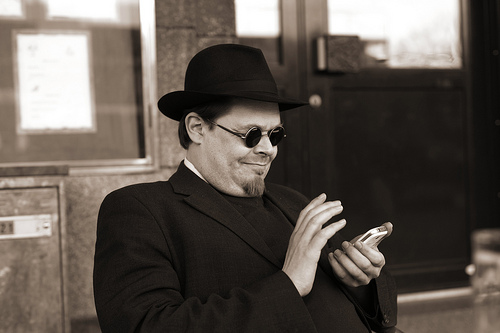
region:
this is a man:
[74, 55, 381, 332]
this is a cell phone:
[348, 227, 394, 257]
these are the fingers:
[285, 197, 345, 283]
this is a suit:
[140, 201, 232, 296]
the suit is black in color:
[154, 199, 206, 277]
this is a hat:
[202, 42, 273, 89]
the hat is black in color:
[210, 46, 263, 86]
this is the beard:
[246, 174, 264, 196]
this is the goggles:
[247, 123, 289, 146]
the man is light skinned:
[206, 140, 233, 170]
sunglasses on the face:
[183, 110, 290, 151]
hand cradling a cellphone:
[330, 212, 400, 289]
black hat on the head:
[145, 38, 330, 133]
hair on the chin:
[240, 174, 277, 201]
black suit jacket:
[59, 158, 409, 330]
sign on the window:
[5, 20, 125, 145]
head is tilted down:
[137, 38, 342, 220]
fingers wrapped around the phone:
[323, 238, 388, 281]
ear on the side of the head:
[184, 112, 210, 149]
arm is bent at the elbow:
[83, 182, 349, 332]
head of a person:
[156, 27, 300, 203]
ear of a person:
[171, 96, 211, 149]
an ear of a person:
[179, 107, 216, 170]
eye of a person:
[238, 121, 265, 156]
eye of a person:
[258, 130, 300, 152]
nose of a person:
[250, 135, 287, 159]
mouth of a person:
[237, 153, 282, 173]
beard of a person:
[232, 171, 287, 203]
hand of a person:
[253, 181, 355, 309]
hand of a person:
[329, 221, 408, 284]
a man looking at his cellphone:
[92, 33, 401, 330]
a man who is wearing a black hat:
[126, 28, 323, 201]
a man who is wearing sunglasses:
[145, 36, 327, 203]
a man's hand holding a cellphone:
[323, 213, 401, 295]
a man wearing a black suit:
[76, 38, 416, 328]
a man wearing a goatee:
[153, 32, 314, 217]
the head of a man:
[174, 95, 288, 200]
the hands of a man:
[268, 182, 403, 307]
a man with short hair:
[138, 39, 300, 201]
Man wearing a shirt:
[215, 178, 368, 331]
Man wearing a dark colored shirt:
[210, 182, 370, 331]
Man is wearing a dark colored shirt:
[207, 180, 374, 332]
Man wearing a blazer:
[91, 154, 412, 326]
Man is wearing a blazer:
[93, 158, 410, 331]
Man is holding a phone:
[349, 217, 387, 256]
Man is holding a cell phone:
[342, 217, 399, 262]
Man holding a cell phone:
[339, 223, 386, 263]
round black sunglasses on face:
[235, 121, 288, 151]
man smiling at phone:
[80, 17, 403, 322]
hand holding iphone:
[337, 208, 402, 298]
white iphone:
[347, 215, 386, 252]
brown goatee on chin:
[238, 173, 270, 198]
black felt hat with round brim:
[150, 43, 310, 130]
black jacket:
[80, 168, 410, 332]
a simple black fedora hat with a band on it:
[153, 40, 320, 115]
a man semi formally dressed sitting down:
[83, 36, 420, 331]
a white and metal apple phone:
[346, 217, 391, 260]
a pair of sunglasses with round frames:
[201, 110, 296, 153]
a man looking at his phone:
[93, 33, 417, 322]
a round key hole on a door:
[309, 88, 326, 113]